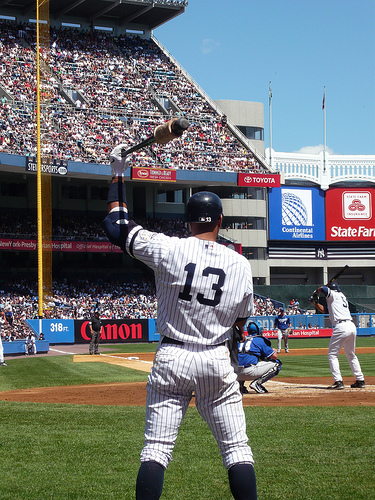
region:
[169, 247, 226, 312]
his number is 13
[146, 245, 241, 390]
his uniform is white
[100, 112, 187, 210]
holding a baseball bat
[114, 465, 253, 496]
his socks are black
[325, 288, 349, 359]
his uniform is white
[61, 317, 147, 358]
the text is red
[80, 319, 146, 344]
it says canon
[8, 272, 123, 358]
many spectators are watching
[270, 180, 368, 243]
the signs are blue and red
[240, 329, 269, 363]
his shirt is white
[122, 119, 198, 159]
Black baseball in man's hand.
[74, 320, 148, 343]
'Canon' advertising on wall.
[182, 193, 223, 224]
Black baseball hat on player.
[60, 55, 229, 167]
Crowds of fans in bleachers.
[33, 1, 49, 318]
tall yellow pole on ball field.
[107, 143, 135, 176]
White Nike glove on player.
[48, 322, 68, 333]
Blue wall says '318 ft.'.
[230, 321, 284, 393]
Baseball catcher bending down.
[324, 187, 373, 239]
Red and white 'State Farm' sign.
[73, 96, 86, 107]
People in the stairway of stadium.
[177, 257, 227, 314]
number thirteen on back of striped jersey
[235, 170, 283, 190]
red banner with white toyota advertisement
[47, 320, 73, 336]
blue wall with 318 feet printed it on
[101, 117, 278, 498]
batter raising bat in the air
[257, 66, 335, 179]
two flags on flag poles above field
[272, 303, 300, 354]
player in blue and gray uniform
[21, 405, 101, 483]
green well manicured lawn on field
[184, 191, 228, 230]
black plastic baseball helmet on batter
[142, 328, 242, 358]
dark belt around pinstriped pants on uniform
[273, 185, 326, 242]
blue and white advertisement for continental airlines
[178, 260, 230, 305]
number 13 is on the shirt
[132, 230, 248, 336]
the shirt is white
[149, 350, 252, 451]
the pants are white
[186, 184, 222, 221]
the helmet is black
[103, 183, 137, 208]
the bnad is black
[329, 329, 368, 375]
the pants are white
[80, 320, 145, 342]
canon is the sponsor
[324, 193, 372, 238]
state farm is being advertised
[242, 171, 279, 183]
toyota is being advertised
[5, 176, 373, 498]
the game being played is baseball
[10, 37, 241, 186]
a group of people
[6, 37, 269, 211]
a group of persons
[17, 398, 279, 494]
a green view of grass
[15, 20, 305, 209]
a group of audience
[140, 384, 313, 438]
legs of the man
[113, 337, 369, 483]
a man wearing pants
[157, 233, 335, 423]
a man wearing shirt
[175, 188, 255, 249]
a man wearing cap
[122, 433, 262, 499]
a man wearing socks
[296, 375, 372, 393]
a man wearing shoe